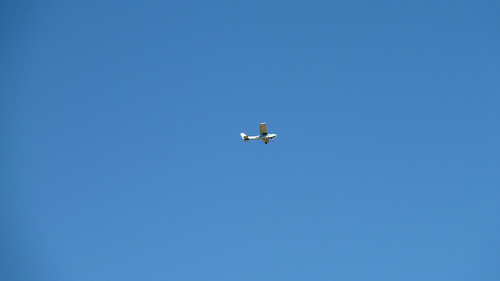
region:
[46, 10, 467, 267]
plane flying under blue sky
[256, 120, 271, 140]
rectangular shape of window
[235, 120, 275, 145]
side of plane reflecting light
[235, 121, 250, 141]
blunt end of tail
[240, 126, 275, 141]
oval shape of body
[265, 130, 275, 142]
tiny dot of a wheel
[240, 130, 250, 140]
dark panel on bottom of tail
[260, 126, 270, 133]
dark window under wing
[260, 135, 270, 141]
black dot against far wing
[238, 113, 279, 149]
horizontal positioning of plane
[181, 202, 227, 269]
part of a the sky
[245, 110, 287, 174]
part of a plane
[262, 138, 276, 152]
part of a wheel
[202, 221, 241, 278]
part fo a the sky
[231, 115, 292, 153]
aeroplane flying in the sky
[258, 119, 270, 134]
turbo engine in the wing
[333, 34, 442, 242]
a clear blue sky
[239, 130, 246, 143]
horizontal and vertical stabilizer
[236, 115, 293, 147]
grey color aeroplane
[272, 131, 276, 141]
front part of the aeroplane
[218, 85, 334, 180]
aeroplane and the sky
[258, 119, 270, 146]
wings and turbo engines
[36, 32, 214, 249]
a clear blue color sky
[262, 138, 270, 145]
wheel of the aeroplane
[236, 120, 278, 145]
Small airplane in the sky.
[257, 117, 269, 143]
Wings of a small airplane.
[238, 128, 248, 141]
Tail end of an airplane.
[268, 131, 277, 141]
Pointy front of an airplane before the wings.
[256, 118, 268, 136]
The longest wing on a airplane.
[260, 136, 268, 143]
Tiny short wing on the body of the plane.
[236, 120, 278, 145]
Very small plane in the blue sky.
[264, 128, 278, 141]
Pointy front of a white plane.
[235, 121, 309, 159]
airplane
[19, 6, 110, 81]
blue sky with no clouds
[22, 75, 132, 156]
blue sky with no clouds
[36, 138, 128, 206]
blue sky with no clouds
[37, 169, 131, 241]
blue sky with no clouds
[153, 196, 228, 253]
blue sky with no clouds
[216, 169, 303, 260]
blue sky with no clouds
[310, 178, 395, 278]
blue sky with no clouds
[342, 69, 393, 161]
blue sky with no clouds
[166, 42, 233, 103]
blue sky with no clouds